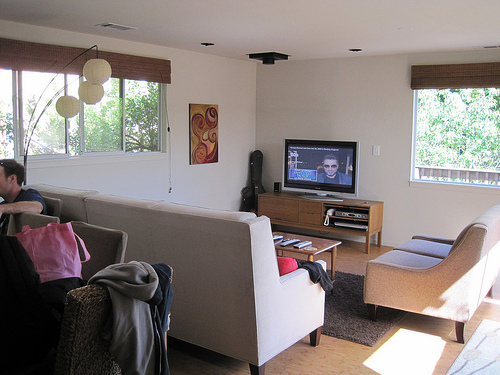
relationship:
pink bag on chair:
[25, 209, 77, 285] [27, 210, 162, 360]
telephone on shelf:
[317, 202, 342, 233] [311, 193, 376, 241]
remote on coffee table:
[291, 239, 312, 251] [313, 237, 335, 251]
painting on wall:
[188, 102, 220, 166] [169, 47, 266, 217]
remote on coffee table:
[293, 240, 313, 249] [270, 228, 341, 283]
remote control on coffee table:
[282, 238, 297, 246] [270, 228, 341, 283]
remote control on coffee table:
[273, 235, 285, 240] [270, 228, 341, 283]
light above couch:
[59, 60, 110, 118] [38, 185, 324, 365]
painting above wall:
[185, 99, 219, 167] [0, 18, 258, 212]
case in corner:
[240, 149, 267, 213] [236, 60, 275, 214]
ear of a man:
[10, 174, 19, 184] [0, 155, 49, 216]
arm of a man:
[1, 194, 42, 216] [0, 156, 45, 221]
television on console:
[275, 125, 364, 195] [257, 189, 384, 254]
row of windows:
[1, 68, 167, 159] [1, 62, 180, 172]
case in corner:
[238, 149, 266, 216] [233, 143, 269, 222]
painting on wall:
[188, 102, 220, 166] [0, 18, 258, 212]